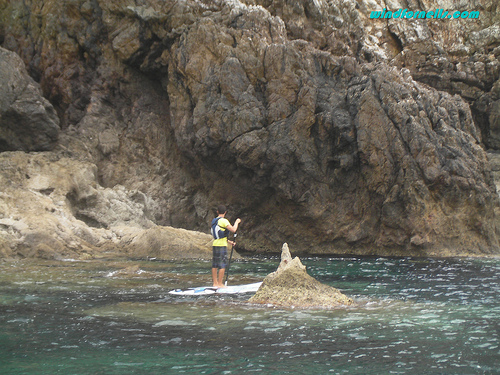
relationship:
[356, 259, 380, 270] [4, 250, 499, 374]
wave on surface of river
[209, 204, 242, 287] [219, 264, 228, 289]
boy has leg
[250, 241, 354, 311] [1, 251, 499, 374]
rock protruding from water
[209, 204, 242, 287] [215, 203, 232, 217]
boy has hair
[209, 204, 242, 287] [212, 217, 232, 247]
boy wears shirt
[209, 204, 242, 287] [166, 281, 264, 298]
boy standing on surfboard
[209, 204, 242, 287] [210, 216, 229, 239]
boy wearing a life vest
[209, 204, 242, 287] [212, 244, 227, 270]
boy wearing shorts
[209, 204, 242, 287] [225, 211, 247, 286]
boy holding paddle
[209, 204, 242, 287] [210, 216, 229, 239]
boy wears life vest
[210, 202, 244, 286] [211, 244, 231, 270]
boy wears shorts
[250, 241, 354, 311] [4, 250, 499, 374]
rock in river